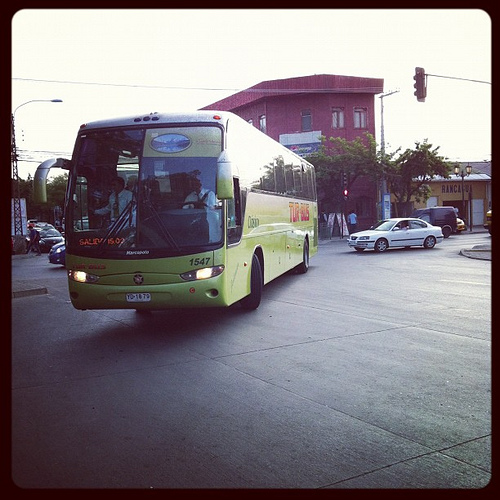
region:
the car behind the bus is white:
[346, 216, 447, 253]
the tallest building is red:
[200, 70, 382, 236]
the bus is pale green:
[33, 110, 330, 328]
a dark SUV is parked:
[407, 202, 459, 243]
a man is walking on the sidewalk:
[21, 221, 46, 262]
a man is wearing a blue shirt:
[344, 209, 366, 234]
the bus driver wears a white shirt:
[177, 172, 219, 213]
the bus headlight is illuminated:
[186, 257, 226, 282]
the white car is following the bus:
[342, 212, 447, 255]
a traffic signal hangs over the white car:
[412, 64, 429, 104]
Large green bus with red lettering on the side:
[63, 118, 318, 309]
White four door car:
[345, 218, 445, 252]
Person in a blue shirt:
[346, 208, 358, 235]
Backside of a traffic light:
[412, 64, 428, 102]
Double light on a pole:
[451, 161, 472, 223]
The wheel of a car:
[374, 236, 389, 253]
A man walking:
[21, 223, 41, 255]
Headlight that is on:
[176, 265, 224, 280]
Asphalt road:
[313, 260, 486, 488]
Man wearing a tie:
[92, 174, 133, 231]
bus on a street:
[26, 95, 331, 336]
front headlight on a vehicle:
[170, 260, 225, 285]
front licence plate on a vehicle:
[115, 285, 155, 300]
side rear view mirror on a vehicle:
[25, 150, 75, 210]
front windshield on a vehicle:
[55, 110, 225, 260]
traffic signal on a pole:
[405, 55, 430, 110]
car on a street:
[340, 210, 450, 262]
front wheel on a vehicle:
[371, 233, 393, 258]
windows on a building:
[326, 98, 376, 136]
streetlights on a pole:
[450, 158, 476, 183]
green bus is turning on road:
[59, 116, 320, 321]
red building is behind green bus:
[225, 65, 380, 220]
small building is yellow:
[395, 170, 486, 240]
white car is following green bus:
[345, 212, 445, 253]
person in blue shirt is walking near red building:
[341, 205, 356, 225]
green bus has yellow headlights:
[67, 266, 222, 281]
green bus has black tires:
[237, 235, 315, 296]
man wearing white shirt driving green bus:
[175, 170, 215, 230]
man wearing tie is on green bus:
[90, 175, 140, 230]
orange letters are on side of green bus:
[278, 198, 311, 224]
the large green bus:
[63, 118, 315, 312]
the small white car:
[347, 216, 442, 251]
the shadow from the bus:
[72, 310, 199, 349]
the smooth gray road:
[206, 325, 456, 470]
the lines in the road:
[310, 300, 452, 347]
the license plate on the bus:
[127, 292, 150, 300]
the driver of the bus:
[186, 177, 212, 209]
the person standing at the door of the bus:
[93, 177, 134, 222]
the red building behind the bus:
[214, 77, 384, 235]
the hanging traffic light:
[414, 68, 489, 99]